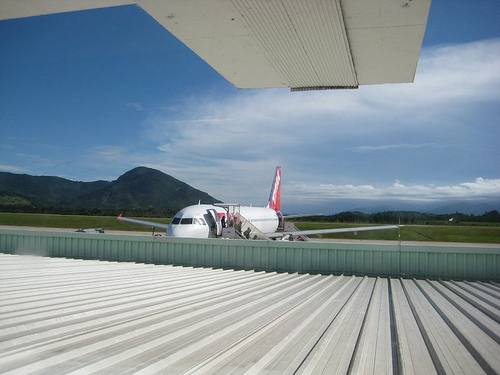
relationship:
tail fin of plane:
[107, 164, 421, 253] [261, 167, 288, 215]